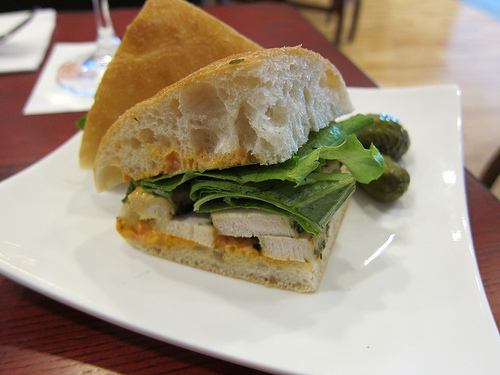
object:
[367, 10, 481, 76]
ground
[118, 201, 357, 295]
bread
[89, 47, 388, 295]
sandwich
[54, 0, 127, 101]
wine glass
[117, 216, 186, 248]
sauce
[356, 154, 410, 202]
pickles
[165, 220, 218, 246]
chicken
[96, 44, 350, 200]
bread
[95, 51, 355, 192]
piece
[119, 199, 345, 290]
piece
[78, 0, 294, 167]
bread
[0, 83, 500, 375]
plate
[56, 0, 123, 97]
glass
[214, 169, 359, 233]
green leaf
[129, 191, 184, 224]
chicken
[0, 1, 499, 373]
table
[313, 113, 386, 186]
lettuce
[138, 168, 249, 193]
lettuce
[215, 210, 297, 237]
chicken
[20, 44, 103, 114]
napkin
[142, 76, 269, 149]
table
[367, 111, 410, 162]
caper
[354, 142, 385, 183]
caper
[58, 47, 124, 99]
bottom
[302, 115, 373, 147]
leaf